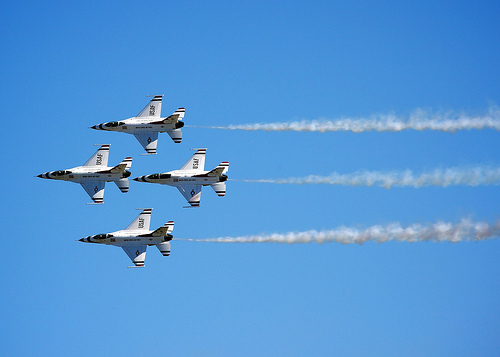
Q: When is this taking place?
A: Daylight.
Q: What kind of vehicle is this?
A: Airplanes.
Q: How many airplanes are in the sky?
A: Four.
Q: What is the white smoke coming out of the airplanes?
A: Smoke.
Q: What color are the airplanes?
A: White and blue.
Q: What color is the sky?
A: Blue.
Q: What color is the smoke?
A: White.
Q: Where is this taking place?
A: In the sky.